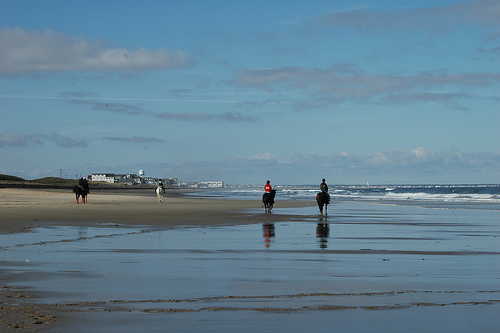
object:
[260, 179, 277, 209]
rider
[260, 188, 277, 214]
horse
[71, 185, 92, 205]
horse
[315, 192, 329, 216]
horse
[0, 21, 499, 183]
sky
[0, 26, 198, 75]
cloud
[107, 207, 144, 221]
sand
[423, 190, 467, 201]
water